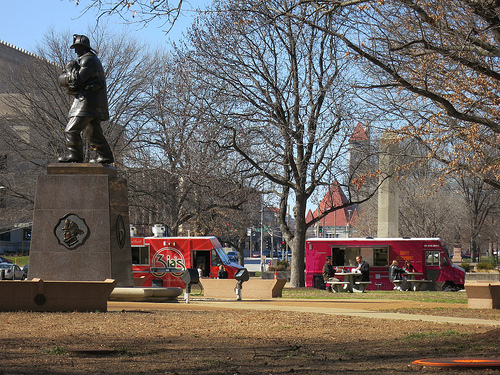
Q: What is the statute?
A: A firefighter.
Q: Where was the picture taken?
A: Park.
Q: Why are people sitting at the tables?
A: Eating a picnic lunch.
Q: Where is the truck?
A: Next to the grass.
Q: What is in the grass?
A: Statue.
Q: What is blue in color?
A: The sky.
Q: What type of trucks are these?
A: Food trucks.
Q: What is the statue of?
A: A fireman.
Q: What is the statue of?
A: A fireman.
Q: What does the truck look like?
A: Red.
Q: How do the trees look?
A: Bare.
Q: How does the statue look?
A: Gray.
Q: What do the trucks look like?
A: Red.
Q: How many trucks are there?
A: Two.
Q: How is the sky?
A: Clear.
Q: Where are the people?
A: Sitting at the picnic tables.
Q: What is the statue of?
A: A firefighter.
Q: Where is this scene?
A: A park.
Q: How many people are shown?
A: Six.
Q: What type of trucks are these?
A: Food trucks.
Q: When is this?
A: During the day.